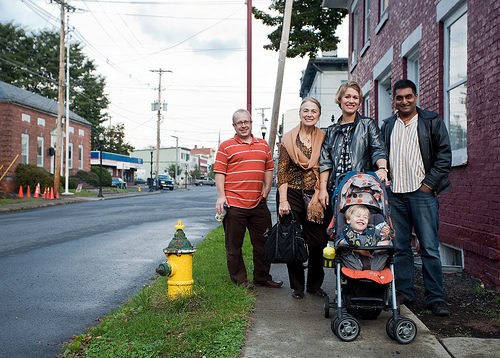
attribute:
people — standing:
[215, 80, 448, 314]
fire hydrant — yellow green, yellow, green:
[158, 217, 196, 298]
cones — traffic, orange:
[18, 184, 54, 197]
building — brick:
[345, 1, 500, 298]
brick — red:
[456, 186, 487, 213]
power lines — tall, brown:
[22, 1, 255, 195]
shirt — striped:
[213, 134, 273, 209]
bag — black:
[261, 210, 307, 264]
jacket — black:
[383, 107, 449, 192]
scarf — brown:
[284, 123, 324, 167]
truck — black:
[149, 173, 173, 190]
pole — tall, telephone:
[147, 65, 167, 185]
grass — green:
[69, 223, 248, 357]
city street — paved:
[0, 186, 226, 341]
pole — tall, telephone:
[50, 1, 74, 200]